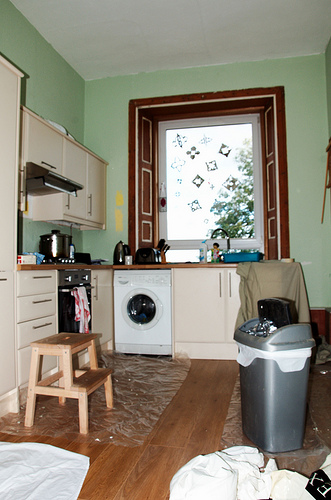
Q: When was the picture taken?
A: Daytime.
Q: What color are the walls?
A: Light green.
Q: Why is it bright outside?
A: It is daytime.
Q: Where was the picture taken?
A: In the room of a house.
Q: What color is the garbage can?
A: Gray.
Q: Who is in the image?
A: Nobody.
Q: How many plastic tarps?
A: Two.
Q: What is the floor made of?
A: Wood.